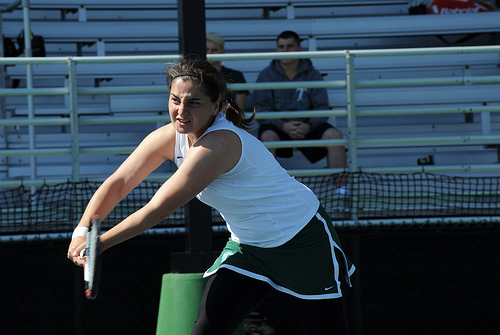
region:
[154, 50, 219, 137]
the head of a woman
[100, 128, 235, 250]
the arm of a woman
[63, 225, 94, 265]
the hand of a woman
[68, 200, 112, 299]
a black tennis racket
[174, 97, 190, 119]
the nose of a woman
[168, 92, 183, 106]
the eye of a woman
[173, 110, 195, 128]
the mouth of a woman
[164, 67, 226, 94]
a black hair band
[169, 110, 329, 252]
a white tank top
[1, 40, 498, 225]
a white metal fence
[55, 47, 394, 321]
The girl is playing tennis.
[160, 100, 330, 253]
The girl wears a white top.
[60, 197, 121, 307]
The girl holds a racquet.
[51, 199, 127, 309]
The girl holds the racquet with both hands.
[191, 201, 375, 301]
The girl wears a skirt.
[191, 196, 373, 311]
The girl's skirt is black and white.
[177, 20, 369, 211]
Two men watch the tennis game.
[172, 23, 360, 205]
The men sit in the stands.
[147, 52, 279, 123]
The tennis player has dark hair.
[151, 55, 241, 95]
The player wears a headband.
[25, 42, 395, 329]
A teenager playing tennis.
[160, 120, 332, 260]
A white tank top.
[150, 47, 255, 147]
The teen has a headband on.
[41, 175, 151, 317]
The tennis racket is being held with both hands.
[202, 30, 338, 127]
Spectators.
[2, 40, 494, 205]
A metal guardrail.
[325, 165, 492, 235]
Black mesh netting.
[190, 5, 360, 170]
The spectators are sitting in the bleachers.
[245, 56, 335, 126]
A hoodie.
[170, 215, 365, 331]
A green skirt and black leggings.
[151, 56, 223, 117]
woman has brown hair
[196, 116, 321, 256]
woman has white shirt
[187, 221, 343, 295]
woman has black shorts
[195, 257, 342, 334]
woman has black leggings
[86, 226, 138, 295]
woman holds tennis racket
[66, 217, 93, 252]
woman has white wristband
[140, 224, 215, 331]
green base of pole behind woman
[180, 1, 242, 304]
pole behind woman is black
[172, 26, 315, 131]
two people behind woman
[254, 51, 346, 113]
man has blue jacket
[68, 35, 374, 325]
a young woman playing tennis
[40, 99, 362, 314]
a young woman wearing a white shirt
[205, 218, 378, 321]
a young woman wearing a tennis skirt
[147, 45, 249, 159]
a young woman with a pony tail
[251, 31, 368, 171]
a young man sitting on the bleachers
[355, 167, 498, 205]
a net in front of the bleachers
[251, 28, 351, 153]
a young man wearing a grey sweatshirt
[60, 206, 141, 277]
a sweat band on the young woman's wrist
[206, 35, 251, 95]
a person sitting in the bleachers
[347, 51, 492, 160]
fence in front of the bleachers